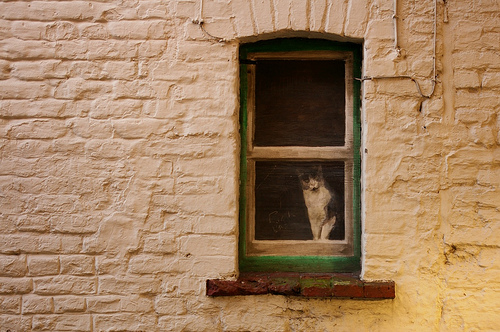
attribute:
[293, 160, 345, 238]
cat — black, white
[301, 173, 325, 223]
cat — black, white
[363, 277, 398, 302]
brick — red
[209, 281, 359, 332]
framed — green